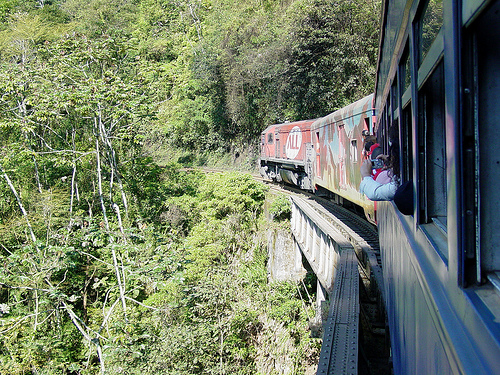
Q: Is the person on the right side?
A: Yes, the person is on the right of the image.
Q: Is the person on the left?
A: No, the person is on the right of the image.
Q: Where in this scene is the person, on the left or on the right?
A: The person is on the right of the image.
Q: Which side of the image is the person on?
A: The person is on the right of the image.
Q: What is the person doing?
A: The person is taking a picture.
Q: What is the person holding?
A: The person is holding the camera.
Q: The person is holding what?
A: The person is holding the camera.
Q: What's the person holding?
A: The person is holding the camera.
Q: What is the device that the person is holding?
A: The device is a camera.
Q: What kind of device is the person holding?
A: The person is holding the camera.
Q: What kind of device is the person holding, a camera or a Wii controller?
A: The person is holding a camera.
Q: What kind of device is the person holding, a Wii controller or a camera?
A: The person is holding a camera.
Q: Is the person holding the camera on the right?
A: Yes, the person is holding the camera.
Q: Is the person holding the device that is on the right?
A: Yes, the person is holding the camera.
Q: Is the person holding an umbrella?
A: No, the person is holding the camera.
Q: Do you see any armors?
A: No, there are no armors.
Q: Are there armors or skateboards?
A: No, there are no armors or skateboards.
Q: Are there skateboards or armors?
A: No, there are no armors or skateboards.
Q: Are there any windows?
A: Yes, there is a window.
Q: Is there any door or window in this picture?
A: Yes, there is a window.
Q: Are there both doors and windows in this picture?
A: Yes, there are both a window and doors.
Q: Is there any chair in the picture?
A: No, there are no chairs.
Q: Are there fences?
A: Yes, there is a fence.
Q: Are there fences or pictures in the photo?
A: Yes, there is a fence.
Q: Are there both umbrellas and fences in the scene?
A: No, there is a fence but no umbrellas.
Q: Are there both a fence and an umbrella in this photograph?
A: No, there is a fence but no umbrellas.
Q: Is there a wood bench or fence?
A: Yes, there is a wood fence.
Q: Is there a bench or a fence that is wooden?
A: Yes, the fence is wooden.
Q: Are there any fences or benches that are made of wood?
A: Yes, the fence is made of wood.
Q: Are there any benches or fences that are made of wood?
A: Yes, the fence is made of wood.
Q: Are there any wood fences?
A: Yes, there is a wood fence.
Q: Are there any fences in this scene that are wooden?
A: Yes, there is a fence that is wooden.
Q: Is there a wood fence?
A: Yes, there is a fence that is made of wood.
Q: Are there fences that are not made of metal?
A: Yes, there is a fence that is made of wood.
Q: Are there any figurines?
A: No, there are no figurines.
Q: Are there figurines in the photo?
A: No, there are no figurines.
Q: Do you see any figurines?
A: No, there are no figurines.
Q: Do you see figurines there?
A: No, there are no figurines.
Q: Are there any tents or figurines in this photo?
A: No, there are no figurines or tents.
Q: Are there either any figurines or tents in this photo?
A: No, there are no figurines or tents.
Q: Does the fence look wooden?
A: Yes, the fence is wooden.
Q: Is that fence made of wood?
A: Yes, the fence is made of wood.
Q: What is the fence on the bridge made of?
A: The fence is made of wood.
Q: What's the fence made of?
A: The fence is made of wood.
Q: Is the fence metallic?
A: No, the fence is wooden.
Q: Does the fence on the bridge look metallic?
A: No, the fence is wooden.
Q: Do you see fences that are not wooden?
A: No, there is a fence but it is wooden.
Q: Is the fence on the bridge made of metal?
A: No, the fence is made of wood.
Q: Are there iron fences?
A: No, there is a fence but it is made of wood.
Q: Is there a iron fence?
A: No, there is a fence but it is made of wood.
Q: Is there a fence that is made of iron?
A: No, there is a fence but it is made of wood.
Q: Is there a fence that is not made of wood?
A: No, there is a fence but it is made of wood.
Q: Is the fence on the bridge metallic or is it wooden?
A: The fence is wooden.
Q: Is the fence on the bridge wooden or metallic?
A: The fence is wooden.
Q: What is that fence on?
A: The fence is on the bridge.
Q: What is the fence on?
A: The fence is on the bridge.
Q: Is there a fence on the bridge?
A: Yes, there is a fence on the bridge.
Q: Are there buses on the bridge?
A: No, there is a fence on the bridge.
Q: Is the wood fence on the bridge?
A: Yes, the fence is on the bridge.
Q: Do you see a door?
A: Yes, there is a door.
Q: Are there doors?
A: Yes, there is a door.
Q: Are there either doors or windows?
A: Yes, there is a door.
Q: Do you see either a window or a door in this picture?
A: Yes, there is a door.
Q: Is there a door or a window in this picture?
A: Yes, there is a door.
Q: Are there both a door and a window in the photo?
A: Yes, there are both a door and a window.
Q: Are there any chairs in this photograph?
A: No, there are no chairs.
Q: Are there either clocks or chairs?
A: No, there are no chairs or clocks.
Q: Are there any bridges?
A: Yes, there is a bridge.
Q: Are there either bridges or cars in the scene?
A: Yes, there is a bridge.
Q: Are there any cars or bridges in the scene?
A: Yes, there is a bridge.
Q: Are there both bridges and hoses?
A: No, there is a bridge but no hoses.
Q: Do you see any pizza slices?
A: No, there are no pizza slices.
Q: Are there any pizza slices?
A: No, there are no pizza slices.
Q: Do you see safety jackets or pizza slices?
A: No, there are no pizza slices or safety jackets.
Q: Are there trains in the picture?
A: Yes, there is a train.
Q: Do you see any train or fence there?
A: Yes, there is a train.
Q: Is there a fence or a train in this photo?
A: Yes, there is a train.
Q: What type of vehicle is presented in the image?
A: The vehicle is a train.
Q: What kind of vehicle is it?
A: The vehicle is a train.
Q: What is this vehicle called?
A: This is a train.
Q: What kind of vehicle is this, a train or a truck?
A: This is a train.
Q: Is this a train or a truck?
A: This is a train.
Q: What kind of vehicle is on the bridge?
A: The vehicle is a train.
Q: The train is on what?
A: The train is on the bridge.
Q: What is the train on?
A: The train is on the bridge.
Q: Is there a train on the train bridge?
A: Yes, there is a train on the bridge.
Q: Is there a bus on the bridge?
A: No, there is a train on the bridge.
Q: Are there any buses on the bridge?
A: No, there is a train on the bridge.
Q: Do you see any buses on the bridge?
A: No, there is a train on the bridge.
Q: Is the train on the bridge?
A: Yes, the train is on the bridge.